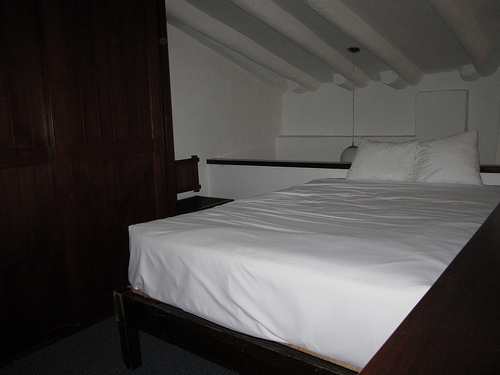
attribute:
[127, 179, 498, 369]
sheets — white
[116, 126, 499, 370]
bed — small, thick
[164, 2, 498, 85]
ceiling — sloped, white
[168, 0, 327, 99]
light — hanging, globe, white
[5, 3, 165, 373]
paneling — wood, dark brown, dark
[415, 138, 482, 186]
pillow — white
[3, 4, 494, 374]
room — small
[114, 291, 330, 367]
bed frame — brown, wood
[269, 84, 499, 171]
wall — white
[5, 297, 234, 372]
carpet — gray